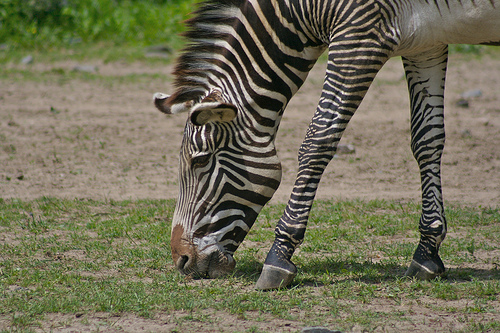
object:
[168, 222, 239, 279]
snout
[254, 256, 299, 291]
hoof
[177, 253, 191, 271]
nostril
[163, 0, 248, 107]
mane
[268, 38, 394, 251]
legs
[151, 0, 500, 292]
zebra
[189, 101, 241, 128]
ear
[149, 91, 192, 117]
ear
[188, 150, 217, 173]
eye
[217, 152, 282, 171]
pattern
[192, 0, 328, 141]
neck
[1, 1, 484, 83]
grass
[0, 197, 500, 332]
grass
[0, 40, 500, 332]
ground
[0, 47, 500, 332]
field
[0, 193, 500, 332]
green grass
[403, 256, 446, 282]
hoof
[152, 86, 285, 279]
head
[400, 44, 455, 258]
leg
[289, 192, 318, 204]
stripes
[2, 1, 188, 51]
bushes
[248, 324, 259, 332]
little grass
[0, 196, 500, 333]
section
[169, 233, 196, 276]
nose